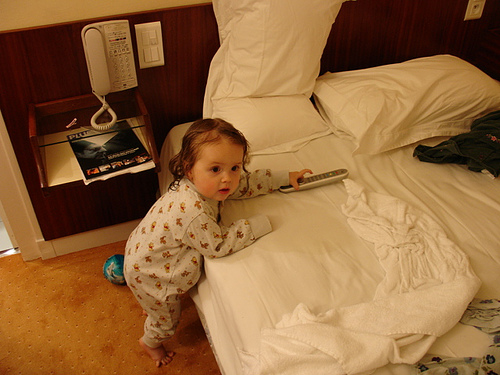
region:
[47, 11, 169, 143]
Home phone is on the wall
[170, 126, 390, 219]
Young girl is holding a remote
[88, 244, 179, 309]
A blue ball is behind young girl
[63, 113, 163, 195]
A magazine is in the background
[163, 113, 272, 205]
Young girls hair is brown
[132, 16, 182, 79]
Light switches are on the wall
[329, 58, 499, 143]
A white pillow is on the bed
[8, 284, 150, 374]
Carpet is light brown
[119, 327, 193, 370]
Young girl is barefoot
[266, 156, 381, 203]
Remote's colors are gray and white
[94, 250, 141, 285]
green ball on the floor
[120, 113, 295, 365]
little kid in pooh jumper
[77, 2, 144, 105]
white telephone on the wall next to the bed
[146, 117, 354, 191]
kid is holding the remote control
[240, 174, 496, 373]
white towel wadded up on the bed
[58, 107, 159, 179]
magazine beside the bed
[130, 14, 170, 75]
switches on the wall beside the bed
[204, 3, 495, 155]
white pillows on the bed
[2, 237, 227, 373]
orange carpet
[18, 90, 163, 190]
shelf mounted on the wall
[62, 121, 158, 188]
Magazine next to the bed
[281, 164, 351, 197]
Remote in child's hand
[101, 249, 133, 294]
Ball on the ground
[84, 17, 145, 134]
Phone on the wall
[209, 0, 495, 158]
Pillows on the bed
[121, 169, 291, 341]
Onesie that the child is wearing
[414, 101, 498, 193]
Clothing on the bed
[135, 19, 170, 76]
Switch on wall next to phone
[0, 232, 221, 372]
The carpeted floor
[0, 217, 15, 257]
White floor only partially seen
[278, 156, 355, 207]
This television remote is cream and gray in color.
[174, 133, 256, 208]
The little girl has a puzzled look on her tiny face.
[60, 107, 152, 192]
There is a television channel guide on the endtable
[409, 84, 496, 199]
Dark gray pajamas are simply tossed onto the bed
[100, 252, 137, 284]
There is a tiny ball on the floor blue and white in color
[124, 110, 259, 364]
The little girl is wearing a pajama set with Winnie-the-Pooh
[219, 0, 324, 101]
This pillow is white with a rather firm consistency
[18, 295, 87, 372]
This carpeting is an orange color and is rather off-putting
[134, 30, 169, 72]
The light switch case has at least four different levers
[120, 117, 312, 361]
baby standing by a bed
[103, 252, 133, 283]
small blue ball on the floor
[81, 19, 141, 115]
telephone hanging on the wall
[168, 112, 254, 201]
baby's wet curly hair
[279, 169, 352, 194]
silver remote control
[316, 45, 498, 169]
white pillow on the bed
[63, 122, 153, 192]
magazine on a side table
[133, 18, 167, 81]
white light switch by the bed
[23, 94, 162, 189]
small brown shelf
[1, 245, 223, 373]
brown patterned carpet